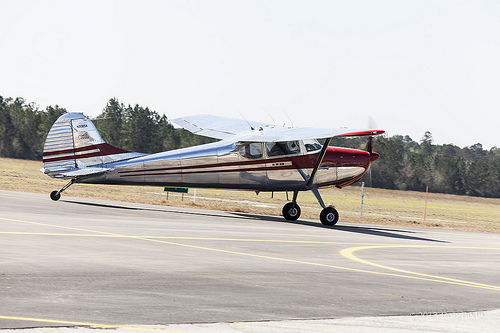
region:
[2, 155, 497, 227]
A grassy landscape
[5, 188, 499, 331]
An asphalt runway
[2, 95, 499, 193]
A line of trees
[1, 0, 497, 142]
A cloudy sky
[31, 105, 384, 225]
A silver and red airplane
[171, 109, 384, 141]
the wings of the airplane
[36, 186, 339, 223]
the wheels on the airplane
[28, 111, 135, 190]
The tail wing of the plane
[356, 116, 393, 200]
the propeller of the plane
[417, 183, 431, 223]
An orange pylon in the grass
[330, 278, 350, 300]
part of a court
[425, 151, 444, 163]
part of a forest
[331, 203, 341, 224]
part of a wheel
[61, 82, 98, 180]
back of a plane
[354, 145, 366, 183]
tip of a plane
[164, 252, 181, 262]
edge of a court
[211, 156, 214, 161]
side of a plane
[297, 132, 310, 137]
side wing of a plane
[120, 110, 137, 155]
tip of a tree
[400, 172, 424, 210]
part of a fence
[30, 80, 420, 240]
red and silver airplane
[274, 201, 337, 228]
two wheels of the airplane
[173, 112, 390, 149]
wings of the airplane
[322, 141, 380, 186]
red nose of the airplane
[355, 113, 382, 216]
moving propellers on the plane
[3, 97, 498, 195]
line of trees in the background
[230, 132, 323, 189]
cockpit of the plane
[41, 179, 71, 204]
back wheel of plane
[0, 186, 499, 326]
runway the plane is sitting on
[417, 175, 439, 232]
orange pole sticking out of the ground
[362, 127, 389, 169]
The propeller on the front of the plane.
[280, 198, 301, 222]
The wheel on the left.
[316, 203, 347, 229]
The wheel on the right.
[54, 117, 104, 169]
The tail of the plane.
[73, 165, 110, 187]
The wing on the tail of the plane.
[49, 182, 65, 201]
The back wheel of the plane.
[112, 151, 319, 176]
The stripes on the side of the plane.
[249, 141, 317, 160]
The windows on the plane.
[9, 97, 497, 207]
The trees in the distance.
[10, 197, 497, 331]
The yellow lines and circles on the ground.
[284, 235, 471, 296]
yellow lines painted on aircraft runway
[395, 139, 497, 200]
row of trees with green leaves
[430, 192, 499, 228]
field covered in grass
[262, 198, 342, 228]
black aircraft landing wheels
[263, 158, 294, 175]
black writing on side of aircraft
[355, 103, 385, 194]
black propeller on front of aircraft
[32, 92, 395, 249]
silver and red aircraft on runway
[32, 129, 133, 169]
red stripe on tail fin of aircraft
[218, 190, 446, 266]
shadow of aircraft on ground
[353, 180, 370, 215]
silver metal fence post